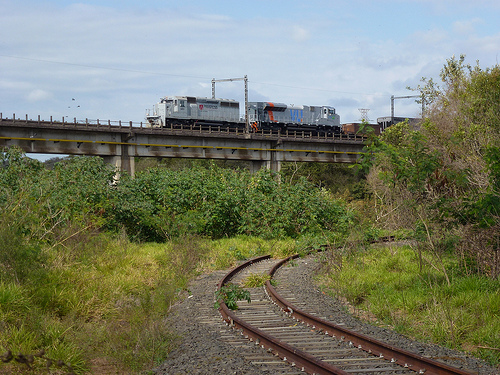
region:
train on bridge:
[0, 111, 385, 188]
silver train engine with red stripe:
[247, 102, 339, 137]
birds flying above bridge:
[70, 96, 75, 101]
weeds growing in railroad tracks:
[217, 281, 250, 307]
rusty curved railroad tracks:
[212, 233, 448, 373]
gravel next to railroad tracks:
[274, 253, 499, 373]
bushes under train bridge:
[3, 144, 355, 240]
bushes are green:
[12, 145, 355, 239]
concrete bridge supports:
[103, 155, 136, 182]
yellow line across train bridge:
[0, 135, 370, 155]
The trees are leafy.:
[384, 126, 496, 276]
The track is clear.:
[208, 235, 395, 374]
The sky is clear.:
[54, 30, 162, 115]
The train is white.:
[141, 79, 242, 134]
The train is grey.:
[246, 80, 343, 147]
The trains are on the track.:
[146, 77, 339, 148]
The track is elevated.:
[27, 96, 434, 185]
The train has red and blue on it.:
[241, 90, 368, 133]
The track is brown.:
[13, 107, 421, 190]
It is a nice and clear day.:
[13, 5, 498, 317]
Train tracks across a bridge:
[35, 107, 360, 182]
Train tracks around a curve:
[183, 226, 425, 371]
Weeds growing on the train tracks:
[203, 253, 301, 324]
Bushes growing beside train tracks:
[78, 146, 385, 259]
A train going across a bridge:
[127, 77, 384, 176]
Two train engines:
[118, 82, 360, 152]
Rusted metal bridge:
[11, 120, 288, 167]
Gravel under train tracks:
[161, 281, 337, 373]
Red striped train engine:
[241, 90, 341, 135]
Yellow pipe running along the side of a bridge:
[1, 123, 368, 168]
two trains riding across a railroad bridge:
[8, 89, 367, 149]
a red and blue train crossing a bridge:
[250, 95, 360, 134]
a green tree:
[126, 159, 241, 237]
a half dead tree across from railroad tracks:
[378, 67, 492, 274]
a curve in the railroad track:
[198, 236, 451, 371]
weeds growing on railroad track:
[169, 215, 479, 371]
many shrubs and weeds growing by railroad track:
[7, 130, 407, 346]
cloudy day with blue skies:
[0, 0, 430, 70]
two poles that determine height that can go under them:
[388, 87, 437, 124]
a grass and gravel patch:
[314, 240, 491, 365]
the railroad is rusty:
[137, 228, 299, 360]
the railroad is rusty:
[211, 202, 302, 369]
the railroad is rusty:
[241, 248, 308, 369]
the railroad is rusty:
[235, 308, 304, 365]